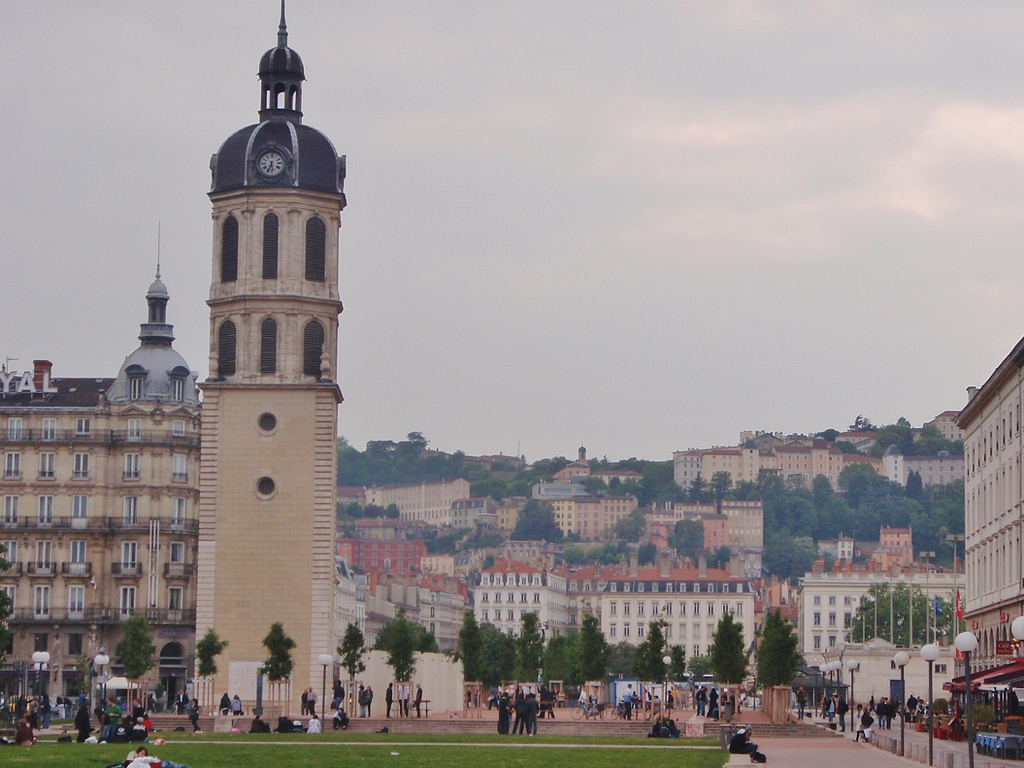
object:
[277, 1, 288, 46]
spire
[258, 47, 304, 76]
dome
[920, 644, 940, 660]
globe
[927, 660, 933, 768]
utility pole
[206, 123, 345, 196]
dome roof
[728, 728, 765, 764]
person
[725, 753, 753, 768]
curb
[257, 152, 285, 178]
clock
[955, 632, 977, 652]
light ball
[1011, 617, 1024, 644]
light ball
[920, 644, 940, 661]
light ball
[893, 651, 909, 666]
light ball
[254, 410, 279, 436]
circle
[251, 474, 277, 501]
circle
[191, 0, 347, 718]
building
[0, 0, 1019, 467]
sky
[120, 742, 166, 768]
person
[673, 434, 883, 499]
buildings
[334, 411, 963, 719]
city hill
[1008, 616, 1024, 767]
light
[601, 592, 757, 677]
building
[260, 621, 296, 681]
leaves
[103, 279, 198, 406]
dome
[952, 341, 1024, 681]
building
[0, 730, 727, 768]
grass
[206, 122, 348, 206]
roof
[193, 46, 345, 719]
tower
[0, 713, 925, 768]
courtyard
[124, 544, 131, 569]
window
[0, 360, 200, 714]
building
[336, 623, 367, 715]
tree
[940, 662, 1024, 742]
awning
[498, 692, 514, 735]
person